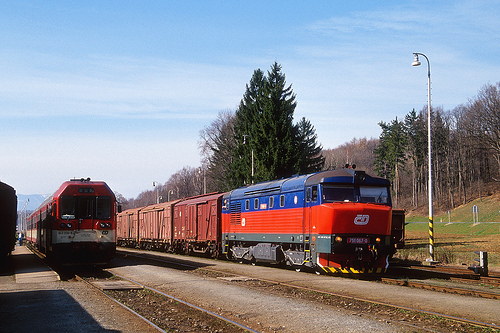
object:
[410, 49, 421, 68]
light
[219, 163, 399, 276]
engine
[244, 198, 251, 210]
window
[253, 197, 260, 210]
window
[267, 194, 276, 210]
window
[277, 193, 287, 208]
window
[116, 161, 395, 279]
train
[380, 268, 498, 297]
track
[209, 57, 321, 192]
tree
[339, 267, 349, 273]
yellow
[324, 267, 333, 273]
black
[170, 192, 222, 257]
car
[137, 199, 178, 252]
car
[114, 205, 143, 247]
car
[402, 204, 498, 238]
grass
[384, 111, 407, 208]
tree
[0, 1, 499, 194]
sky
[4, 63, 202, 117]
cloud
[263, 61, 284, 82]
top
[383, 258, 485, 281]
shadow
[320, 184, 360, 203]
window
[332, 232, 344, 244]
light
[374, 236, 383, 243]
light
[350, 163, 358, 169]
horn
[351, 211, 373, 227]
logo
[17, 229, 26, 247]
man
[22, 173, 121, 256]
train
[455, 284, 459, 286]
ballast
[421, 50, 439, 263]
pole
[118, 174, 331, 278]
side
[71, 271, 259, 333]
track